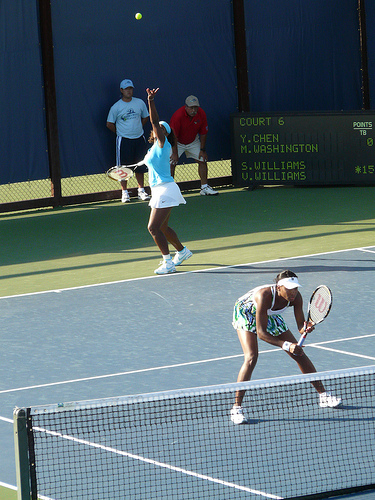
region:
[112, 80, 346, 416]
two women on a tennis court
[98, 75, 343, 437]
two women playing tennis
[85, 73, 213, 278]
the woman holding the tennis racket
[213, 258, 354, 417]
the woman holding the tennis racket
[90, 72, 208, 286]
the woman is serving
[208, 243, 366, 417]
the woman is croutching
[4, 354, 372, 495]
the net on the court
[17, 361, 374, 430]
the white trim on the net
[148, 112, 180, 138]
the woman wearing a head band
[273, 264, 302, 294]
the woman wearing a visor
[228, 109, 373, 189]
black tennis scoreboard with green lettering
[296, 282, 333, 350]
white, red and blue tennis racket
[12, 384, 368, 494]
net on a tennis court with white top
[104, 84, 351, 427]
two women playing doubles tennis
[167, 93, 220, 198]
man with white shorts and red shirt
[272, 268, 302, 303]
woman's head with white sun visor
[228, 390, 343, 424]
white pair of tennis shoes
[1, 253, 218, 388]
gray and green tennis court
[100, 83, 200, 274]
woman preparing to make a tennis serve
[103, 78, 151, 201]
man with white hat and shirt and dark shorts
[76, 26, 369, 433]
two women on a doubles tennis team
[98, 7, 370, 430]
two black women playing tennis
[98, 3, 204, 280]
a women ready to serve the ball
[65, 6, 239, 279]
a women serving the ball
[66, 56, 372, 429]
two athletes focused on their match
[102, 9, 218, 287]
a woman focused on her serve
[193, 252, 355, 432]
a tennis player prepared to hit the return ball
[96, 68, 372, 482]
two tennis players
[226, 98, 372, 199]
a tennis scoreboard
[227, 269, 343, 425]
a tennis player on a tennis court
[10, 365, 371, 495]
a tennis court net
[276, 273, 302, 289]
woman wearing a white visor hat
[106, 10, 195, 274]
tennis player about to hit a ball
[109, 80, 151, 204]
man standing against a blue tarp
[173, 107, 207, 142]
man wearing a red shirt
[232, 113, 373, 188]
a digital display on a tennis cout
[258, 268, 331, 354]
a woman holding a tennis racket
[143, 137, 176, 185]
woman wearing a blue shirt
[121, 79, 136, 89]
man wearing a white cap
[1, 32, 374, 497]
doubles women's tennis match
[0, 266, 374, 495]
female tennis player near net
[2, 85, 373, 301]
female tennis player behind baseline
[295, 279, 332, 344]
tennis racket with Wilson logo on strings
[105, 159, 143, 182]
tennis racket with Wilson logo on strings held by the player who is serving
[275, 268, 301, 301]
sun visor on head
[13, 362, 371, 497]
net across tennis court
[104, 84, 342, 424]
the Williams sisters playing tennis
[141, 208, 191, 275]
white tennis skirt, bare legs, and white shoes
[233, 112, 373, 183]
scoreboard at a doubles tennis match